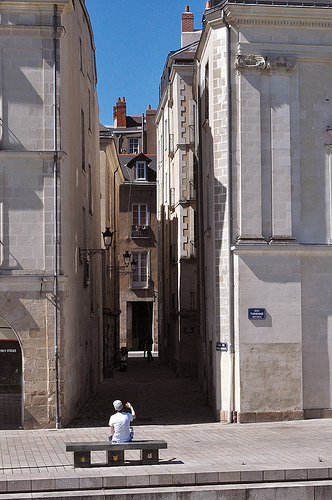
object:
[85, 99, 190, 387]
buildings together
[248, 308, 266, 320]
poster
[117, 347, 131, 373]
motorcycle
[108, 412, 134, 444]
shirt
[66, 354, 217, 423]
floor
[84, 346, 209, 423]
passage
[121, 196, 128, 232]
brown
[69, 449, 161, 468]
brandigs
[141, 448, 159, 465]
sand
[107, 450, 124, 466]
sand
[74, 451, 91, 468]
sand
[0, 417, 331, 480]
floor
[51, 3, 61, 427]
pipe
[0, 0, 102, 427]
building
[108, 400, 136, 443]
guy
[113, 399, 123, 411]
hat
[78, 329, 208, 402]
alley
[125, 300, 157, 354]
doorway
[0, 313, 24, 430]
doorway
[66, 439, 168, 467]
bench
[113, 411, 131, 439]
back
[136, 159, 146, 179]
window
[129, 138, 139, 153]
window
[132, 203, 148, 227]
window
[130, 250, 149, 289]
window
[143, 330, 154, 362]
person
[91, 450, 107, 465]
cut outs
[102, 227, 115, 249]
lantern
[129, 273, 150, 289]
balcony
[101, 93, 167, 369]
building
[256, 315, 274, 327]
shadow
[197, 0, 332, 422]
building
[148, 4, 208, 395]
building